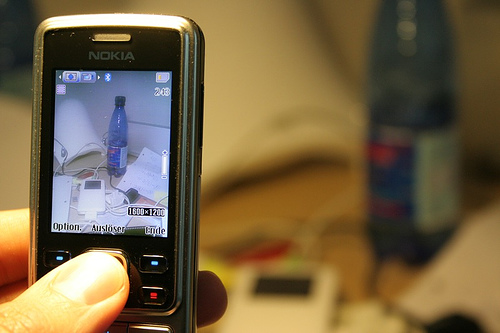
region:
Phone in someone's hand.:
[37, 4, 282, 329]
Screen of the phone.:
[25, 43, 275, 250]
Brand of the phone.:
[75, 46, 173, 81]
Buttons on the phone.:
[50, 220, 160, 289]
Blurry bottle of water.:
[327, 10, 494, 330]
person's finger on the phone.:
[37, 205, 159, 330]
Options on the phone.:
[89, 199, 176, 242]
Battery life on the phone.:
[129, 50, 182, 115]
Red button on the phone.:
[136, 280, 170, 307]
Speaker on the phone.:
[78, 22, 149, 52]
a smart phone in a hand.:
[24, 5, 209, 330]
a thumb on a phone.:
[6, 229, 137, 331]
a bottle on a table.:
[347, 0, 466, 270]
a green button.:
[141, 250, 169, 275]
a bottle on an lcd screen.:
[98, 79, 140, 191]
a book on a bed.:
[191, 236, 357, 328]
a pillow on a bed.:
[32, 0, 491, 193]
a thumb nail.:
[39, 230, 136, 313]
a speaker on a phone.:
[81, 27, 141, 52]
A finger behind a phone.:
[167, 253, 252, 331]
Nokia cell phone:
[19, 20, 184, 253]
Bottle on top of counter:
[91, 87, 148, 183]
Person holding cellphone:
[23, 150, 160, 331]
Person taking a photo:
[11, 12, 182, 328]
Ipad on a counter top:
[82, 177, 115, 212]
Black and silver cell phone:
[14, 21, 217, 265]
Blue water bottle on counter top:
[94, 91, 139, 183]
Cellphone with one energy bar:
[148, 70, 180, 89]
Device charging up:
[80, 172, 109, 229]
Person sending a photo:
[28, 136, 183, 305]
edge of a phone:
[193, 161, 202, 191]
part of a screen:
[113, 94, 142, 127]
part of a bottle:
[398, 219, 410, 251]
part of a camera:
[111, 107, 123, 126]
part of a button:
[156, 291, 177, 293]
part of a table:
[298, 230, 317, 257]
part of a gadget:
[276, 258, 304, 305]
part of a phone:
[53, 216, 63, 245]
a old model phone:
[31, 18, 220, 330]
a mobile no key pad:
[25, 17, 217, 327]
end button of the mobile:
[141, 282, 166, 309]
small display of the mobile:
[50, 67, 172, 230]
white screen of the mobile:
[48, 71, 178, 252]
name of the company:
[74, 30, 144, 71]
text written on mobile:
[79, 45, 151, 70]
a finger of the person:
[18, 255, 139, 332]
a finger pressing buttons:
[23, 265, 132, 331]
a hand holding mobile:
[13, 19, 260, 328]